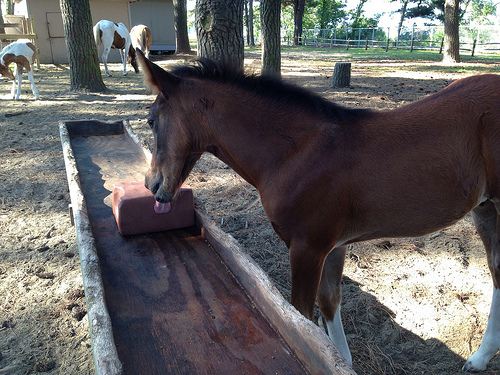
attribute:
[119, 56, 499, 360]
horse — brown, white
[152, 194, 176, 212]
tongue — horse's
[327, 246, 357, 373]
leg — horse's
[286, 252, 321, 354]
leg — horse's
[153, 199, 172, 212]
tongue — horse's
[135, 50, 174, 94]
ear — horse's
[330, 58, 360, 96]
tree — cut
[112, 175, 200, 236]
salt brick — brown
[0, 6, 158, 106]
horse's — in the background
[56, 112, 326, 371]
trough — in front of the horse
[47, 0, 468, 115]
trees — around the horses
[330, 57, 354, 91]
tree stump — short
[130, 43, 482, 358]
pony — standing, brown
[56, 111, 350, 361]
trough — wooden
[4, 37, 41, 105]
horse — brown, white, standing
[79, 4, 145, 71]
horse — brown, white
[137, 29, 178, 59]
horse — white, brown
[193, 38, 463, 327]
horse — brown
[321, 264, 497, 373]
legs — white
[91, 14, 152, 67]
horse — white, brown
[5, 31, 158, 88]
horses — white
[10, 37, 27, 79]
spots — brown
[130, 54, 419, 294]
horse — brown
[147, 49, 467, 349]
horse — brown, young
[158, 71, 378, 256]
horse — healthy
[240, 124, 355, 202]
fur — brown